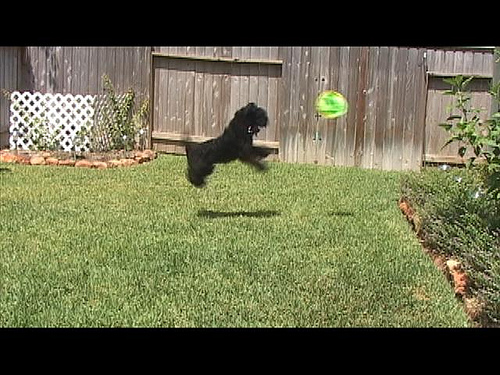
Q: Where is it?
A: This is at the yard.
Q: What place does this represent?
A: It represents the yard.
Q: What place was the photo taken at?
A: It was taken at the yard.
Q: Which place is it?
A: It is a yard.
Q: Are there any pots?
A: No, there are no pots.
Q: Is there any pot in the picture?
A: No, there are no pots.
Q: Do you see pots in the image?
A: No, there are no pots.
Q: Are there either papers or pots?
A: No, there are no pots or papers.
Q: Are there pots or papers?
A: No, there are no pots or papers.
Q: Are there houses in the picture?
A: No, there are no houses.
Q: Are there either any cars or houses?
A: No, there are no houses or cars.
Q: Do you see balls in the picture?
A: Yes, there is a ball.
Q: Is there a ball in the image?
A: Yes, there is a ball.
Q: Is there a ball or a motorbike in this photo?
A: Yes, there is a ball.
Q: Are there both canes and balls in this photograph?
A: No, there is a ball but no canes.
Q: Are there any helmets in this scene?
A: No, there are no helmets.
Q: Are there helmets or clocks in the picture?
A: No, there are no helmets or clocks.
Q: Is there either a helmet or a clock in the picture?
A: No, there are no helmets or clocks.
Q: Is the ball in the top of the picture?
A: Yes, the ball is in the top of the image.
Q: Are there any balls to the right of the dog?
A: Yes, there is a ball to the right of the dog.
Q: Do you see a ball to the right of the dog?
A: Yes, there is a ball to the right of the dog.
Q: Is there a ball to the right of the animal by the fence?
A: Yes, there is a ball to the right of the dog.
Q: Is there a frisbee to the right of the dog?
A: No, there is a ball to the right of the dog.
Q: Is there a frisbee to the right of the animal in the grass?
A: No, there is a ball to the right of the dog.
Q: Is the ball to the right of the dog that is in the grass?
A: Yes, the ball is to the right of the dog.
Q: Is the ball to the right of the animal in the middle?
A: Yes, the ball is to the right of the dog.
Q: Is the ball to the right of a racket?
A: No, the ball is to the right of the dog.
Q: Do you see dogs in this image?
A: Yes, there is a dog.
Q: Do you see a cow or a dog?
A: Yes, there is a dog.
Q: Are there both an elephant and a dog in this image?
A: No, there is a dog but no elephants.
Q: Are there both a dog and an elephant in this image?
A: No, there is a dog but no elephants.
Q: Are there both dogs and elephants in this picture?
A: No, there is a dog but no elephants.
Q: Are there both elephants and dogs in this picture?
A: No, there is a dog but no elephants.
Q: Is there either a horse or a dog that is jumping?
A: Yes, the dog is jumping.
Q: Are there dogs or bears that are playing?
A: Yes, the dog is playing.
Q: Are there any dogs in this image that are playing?
A: Yes, there is a dog that is playing.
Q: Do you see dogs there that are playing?
A: Yes, there is a dog that is playing.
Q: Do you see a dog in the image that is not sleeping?
A: Yes, there is a dog that is playing .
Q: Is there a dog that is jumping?
A: Yes, there is a dog that is jumping.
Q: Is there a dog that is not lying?
A: Yes, there is a dog that is jumping.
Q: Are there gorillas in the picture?
A: No, there are no gorillas.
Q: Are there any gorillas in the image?
A: No, there are no gorillas.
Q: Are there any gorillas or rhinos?
A: No, there are no gorillas or rhinos.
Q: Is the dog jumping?
A: Yes, the dog is jumping.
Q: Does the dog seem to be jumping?
A: Yes, the dog is jumping.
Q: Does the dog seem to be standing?
A: No, the dog is jumping.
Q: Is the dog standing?
A: No, the dog is jumping.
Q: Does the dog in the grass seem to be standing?
A: No, the dog is jumping.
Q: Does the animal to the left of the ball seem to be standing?
A: No, the dog is jumping.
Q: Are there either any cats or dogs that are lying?
A: No, there is a dog but it is jumping.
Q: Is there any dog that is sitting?
A: No, there is a dog but it is jumping.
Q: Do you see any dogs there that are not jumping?
A: No, there is a dog but it is jumping.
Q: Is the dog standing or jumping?
A: The dog is jumping.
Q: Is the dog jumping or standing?
A: The dog is jumping.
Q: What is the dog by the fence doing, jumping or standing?
A: The dog is jumping.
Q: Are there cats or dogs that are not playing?
A: No, there is a dog but it is playing.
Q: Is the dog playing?
A: Yes, the dog is playing.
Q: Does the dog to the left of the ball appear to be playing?
A: Yes, the dog is playing.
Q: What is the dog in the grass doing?
A: The dog is playing.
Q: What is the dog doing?
A: The dog is playing.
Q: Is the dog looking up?
A: No, the dog is playing.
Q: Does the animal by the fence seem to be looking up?
A: No, the dog is playing.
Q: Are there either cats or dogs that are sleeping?
A: No, there is a dog but it is playing.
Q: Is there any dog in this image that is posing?
A: No, there is a dog but it is playing.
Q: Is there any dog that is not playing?
A: No, there is a dog but it is playing.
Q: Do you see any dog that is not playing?
A: No, there is a dog but it is playing.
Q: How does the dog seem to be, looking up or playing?
A: The dog is playing.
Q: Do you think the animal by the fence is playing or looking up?
A: The dog is playing.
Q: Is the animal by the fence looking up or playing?
A: The dog is playing.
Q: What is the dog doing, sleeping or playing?
A: The dog is playing.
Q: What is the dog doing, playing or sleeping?
A: The dog is playing.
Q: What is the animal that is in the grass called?
A: The animal is a dog.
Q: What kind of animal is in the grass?
A: The animal is a dog.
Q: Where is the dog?
A: The dog is in the grass.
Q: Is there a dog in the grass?
A: Yes, there is a dog in the grass.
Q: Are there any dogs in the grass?
A: Yes, there is a dog in the grass.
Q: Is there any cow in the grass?
A: No, there is a dog in the grass.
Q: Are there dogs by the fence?
A: Yes, there is a dog by the fence.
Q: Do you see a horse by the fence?
A: No, there is a dog by the fence.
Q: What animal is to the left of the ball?
A: The animal is a dog.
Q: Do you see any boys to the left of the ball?
A: No, there is a dog to the left of the ball.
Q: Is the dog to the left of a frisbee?
A: No, the dog is to the left of the ball.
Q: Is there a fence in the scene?
A: Yes, there is a fence.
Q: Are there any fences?
A: Yes, there is a fence.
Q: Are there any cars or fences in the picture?
A: Yes, there is a fence.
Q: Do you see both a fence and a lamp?
A: No, there is a fence but no lamps.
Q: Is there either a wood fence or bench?
A: Yes, there is a wood fence.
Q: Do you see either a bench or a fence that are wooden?
A: Yes, the fence is wooden.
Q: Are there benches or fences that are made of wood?
A: Yes, the fence is made of wood.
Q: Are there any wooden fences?
A: Yes, there is a wood fence.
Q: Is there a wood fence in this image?
A: Yes, there is a wood fence.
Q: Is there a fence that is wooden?
A: Yes, there is a fence that is wooden.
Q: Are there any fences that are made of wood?
A: Yes, there is a fence that is made of wood.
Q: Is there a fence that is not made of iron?
A: Yes, there is a fence that is made of wood.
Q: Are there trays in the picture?
A: No, there are no trays.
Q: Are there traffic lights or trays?
A: No, there are no trays or traffic lights.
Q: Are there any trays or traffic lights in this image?
A: No, there are no trays or traffic lights.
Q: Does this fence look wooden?
A: Yes, the fence is wooden.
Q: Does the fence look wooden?
A: Yes, the fence is wooden.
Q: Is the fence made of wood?
A: Yes, the fence is made of wood.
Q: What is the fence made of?
A: The fence is made of wood.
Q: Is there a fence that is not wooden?
A: No, there is a fence but it is wooden.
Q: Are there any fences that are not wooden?
A: No, there is a fence but it is wooden.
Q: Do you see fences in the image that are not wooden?
A: No, there is a fence but it is wooden.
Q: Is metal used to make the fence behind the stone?
A: No, the fence is made of wood.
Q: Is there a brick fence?
A: No, there is a fence but it is made of wood.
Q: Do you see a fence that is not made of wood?
A: No, there is a fence but it is made of wood.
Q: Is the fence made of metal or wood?
A: The fence is made of wood.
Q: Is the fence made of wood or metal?
A: The fence is made of wood.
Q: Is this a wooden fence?
A: Yes, this is a wooden fence.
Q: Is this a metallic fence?
A: No, this is a wooden fence.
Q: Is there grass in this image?
A: Yes, there is grass.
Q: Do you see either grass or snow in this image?
A: Yes, there is grass.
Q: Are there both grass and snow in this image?
A: No, there is grass but no snow.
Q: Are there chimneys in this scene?
A: No, there are no chimneys.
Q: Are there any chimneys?
A: No, there are no chimneys.